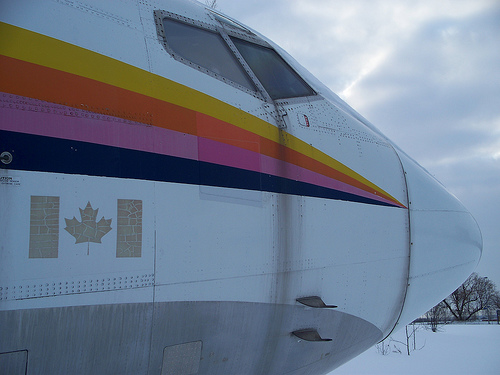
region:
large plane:
[3, 1, 483, 373]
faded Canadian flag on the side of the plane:
[24, 183, 154, 268]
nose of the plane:
[404, 149, 494, 324]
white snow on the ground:
[325, 301, 497, 373]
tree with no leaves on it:
[425, 269, 499, 322]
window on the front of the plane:
[153, 3, 319, 116]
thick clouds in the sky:
[204, 1, 499, 287]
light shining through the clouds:
[343, 46, 383, 107]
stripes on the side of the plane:
[1, 16, 426, 248]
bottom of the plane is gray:
[0, 298, 390, 374]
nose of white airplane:
[401, 155, 483, 327]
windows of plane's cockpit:
[160, 10, 322, 104]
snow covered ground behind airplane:
[346, 297, 499, 374]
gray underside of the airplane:
[6, 301, 381, 373]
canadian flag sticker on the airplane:
[26, 187, 143, 262]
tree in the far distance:
[425, 270, 499, 325]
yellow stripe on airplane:
[2, 18, 413, 194]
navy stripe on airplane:
[2, 130, 396, 209]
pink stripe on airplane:
[2, 90, 393, 202]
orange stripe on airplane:
[2, 57, 404, 202]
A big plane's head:
[83, 5, 461, 369]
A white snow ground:
[413, 325, 489, 372]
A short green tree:
[440, 284, 493, 309]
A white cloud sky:
[449, 143, 494, 215]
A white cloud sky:
[422, 34, 486, 123]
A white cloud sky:
[342, 27, 429, 135]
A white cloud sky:
[254, 9, 338, 37]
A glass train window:
[231, 23, 302, 98]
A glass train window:
[152, 13, 250, 88]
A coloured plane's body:
[45, 37, 367, 229]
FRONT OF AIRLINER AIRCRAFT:
[30, 82, 472, 262]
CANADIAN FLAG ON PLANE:
[29, 202, 145, 237]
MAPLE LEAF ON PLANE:
[73, 209, 108, 245]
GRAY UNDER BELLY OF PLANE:
[257, 314, 387, 369]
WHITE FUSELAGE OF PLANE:
[43, 223, 248, 295]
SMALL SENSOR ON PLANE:
[286, 284, 333, 312]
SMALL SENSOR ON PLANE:
[287, 329, 322, 348]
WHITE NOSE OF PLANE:
[373, 216, 487, 320]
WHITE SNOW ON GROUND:
[404, 324, 499, 370]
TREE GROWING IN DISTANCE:
[452, 279, 484, 341]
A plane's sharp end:
[386, 138, 489, 303]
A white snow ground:
[347, 346, 419, 373]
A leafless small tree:
[444, 287, 499, 317]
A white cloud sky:
[413, 125, 496, 173]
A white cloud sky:
[283, 7, 396, 85]